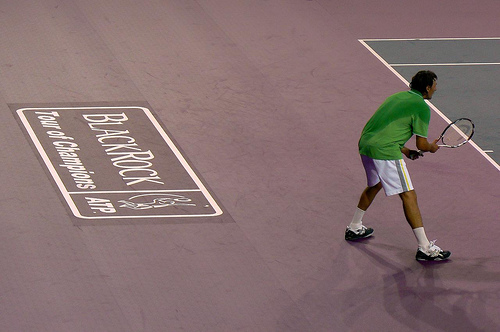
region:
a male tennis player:
[345, 66, 480, 266]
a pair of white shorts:
[360, 148, 413, 198]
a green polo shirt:
[355, 92, 433, 159]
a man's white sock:
[410, 227, 430, 246]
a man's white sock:
[348, 206, 365, 227]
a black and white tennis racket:
[413, 115, 477, 159]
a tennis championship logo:
[9, 98, 231, 222]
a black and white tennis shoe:
[413, 246, 451, 262]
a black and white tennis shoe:
[341, 223, 372, 241]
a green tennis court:
[358, 35, 499, 174]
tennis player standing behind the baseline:
[337, 35, 462, 259]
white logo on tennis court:
[8, 91, 227, 224]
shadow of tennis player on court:
[350, 245, 488, 325]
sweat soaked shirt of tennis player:
[352, 90, 433, 158]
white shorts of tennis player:
[356, 149, 403, 198]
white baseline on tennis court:
[359, 33, 494, 178]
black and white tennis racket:
[430, 117, 470, 156]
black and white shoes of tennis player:
[346, 218, 446, 265]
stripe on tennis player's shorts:
[388, 153, 411, 191]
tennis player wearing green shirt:
[330, 63, 491, 270]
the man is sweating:
[357, 63, 450, 156]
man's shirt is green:
[352, 77, 437, 160]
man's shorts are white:
[353, 146, 433, 188]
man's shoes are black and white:
[333, 218, 484, 288]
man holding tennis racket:
[387, 42, 488, 162]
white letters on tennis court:
[20, 56, 233, 291]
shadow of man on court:
[376, 211, 492, 329]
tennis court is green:
[354, 20, 497, 164]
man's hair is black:
[394, 58, 443, 103]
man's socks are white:
[332, 173, 447, 246]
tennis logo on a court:
[5, 93, 232, 232]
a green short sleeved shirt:
[358, 88, 432, 161]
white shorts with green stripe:
[360, 154, 415, 195]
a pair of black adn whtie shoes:
[344, 220, 452, 260]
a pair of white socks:
[347, 208, 432, 248]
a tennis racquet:
[408, 116, 475, 156]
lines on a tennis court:
[361, 36, 499, 163]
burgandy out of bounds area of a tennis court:
[1, 0, 499, 326]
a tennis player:
[344, 70, 474, 261]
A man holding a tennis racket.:
[350, 70, 485, 272]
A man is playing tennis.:
[345, 66, 482, 278]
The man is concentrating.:
[343, 66, 496, 262]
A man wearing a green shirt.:
[354, 64, 441, 156]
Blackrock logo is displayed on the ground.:
[5, 65, 224, 227]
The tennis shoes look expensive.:
[337, 209, 456, 266]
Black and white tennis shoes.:
[344, 224, 450, 264]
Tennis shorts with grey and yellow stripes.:
[359, 149, 415, 196]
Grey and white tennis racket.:
[432, 110, 477, 156]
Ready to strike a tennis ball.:
[17, 105, 94, 205]